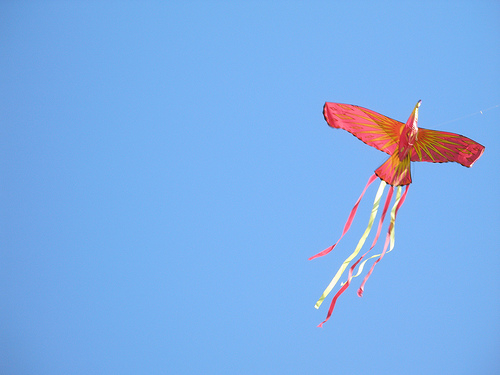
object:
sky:
[2, 1, 478, 371]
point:
[414, 96, 424, 104]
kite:
[291, 96, 484, 332]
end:
[300, 160, 412, 331]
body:
[375, 96, 430, 214]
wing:
[418, 122, 484, 169]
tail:
[293, 158, 438, 329]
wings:
[320, 100, 486, 170]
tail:
[303, 151, 415, 333]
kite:
[299, 92, 484, 337]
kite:
[309, 95, 483, 327]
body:
[389, 115, 423, 161]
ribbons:
[303, 174, 414, 332]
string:
[308, 173, 374, 256]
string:
[312, 181, 371, 246]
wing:
[321, 97, 393, 154]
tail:
[288, 152, 418, 349]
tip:
[321, 99, 332, 124]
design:
[316, 72, 494, 322]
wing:
[413, 123, 483, 171]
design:
[413, 129, 466, 159]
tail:
[303, 149, 418, 328]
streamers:
[303, 172, 413, 332]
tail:
[283, 152, 416, 347]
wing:
[413, 125, 489, 170]